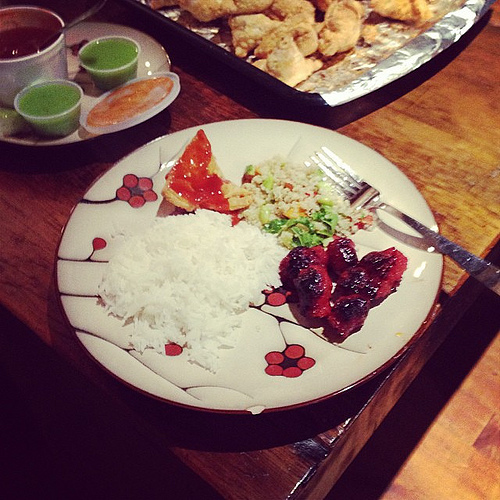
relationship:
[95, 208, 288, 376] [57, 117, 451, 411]
rice on plate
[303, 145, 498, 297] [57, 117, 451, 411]
fork on plate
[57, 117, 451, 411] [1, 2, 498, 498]
plate on table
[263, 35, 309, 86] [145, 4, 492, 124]
pizza roll on pan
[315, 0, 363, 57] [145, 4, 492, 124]
pizza roll on pan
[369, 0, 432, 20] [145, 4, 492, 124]
pizza roll on pan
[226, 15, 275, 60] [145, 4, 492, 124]
pizza roll on pan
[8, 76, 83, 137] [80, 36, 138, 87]
guacamole in cup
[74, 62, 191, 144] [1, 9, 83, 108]
top of container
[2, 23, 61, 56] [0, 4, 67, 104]
sauce in container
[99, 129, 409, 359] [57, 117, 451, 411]
food on plate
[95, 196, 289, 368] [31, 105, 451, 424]
rice on plate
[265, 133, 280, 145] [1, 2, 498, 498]
plate on table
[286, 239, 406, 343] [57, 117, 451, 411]
meat on plate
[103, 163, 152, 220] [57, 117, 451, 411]
rose design on plate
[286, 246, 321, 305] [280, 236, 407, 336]
glaze on food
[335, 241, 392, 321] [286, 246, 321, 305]
glaze on glaze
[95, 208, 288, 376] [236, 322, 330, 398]
rice on plate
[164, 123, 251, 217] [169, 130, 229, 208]
fried wonton with sauce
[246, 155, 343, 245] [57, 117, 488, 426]
vegetables on plate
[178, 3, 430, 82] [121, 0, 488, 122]
wontons on a pan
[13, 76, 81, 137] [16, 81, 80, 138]
container of sauce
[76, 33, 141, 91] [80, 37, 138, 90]
container of sauce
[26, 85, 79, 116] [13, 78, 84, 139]
liquid in cup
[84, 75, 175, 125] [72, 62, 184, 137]
sauce on lid